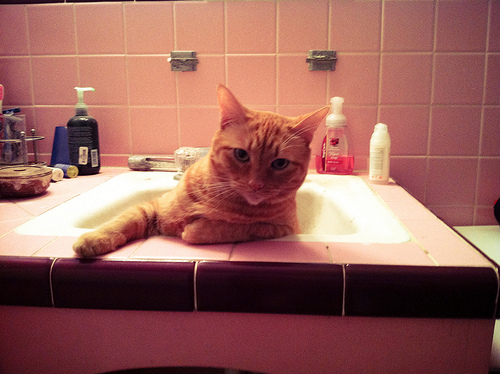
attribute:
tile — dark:
[0, 253, 54, 306]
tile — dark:
[52, 257, 194, 313]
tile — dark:
[195, 259, 343, 315]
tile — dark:
[342, 262, 499, 321]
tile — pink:
[373, 96, 436, 161]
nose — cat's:
[240, 161, 270, 199]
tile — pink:
[377, 2, 441, 57]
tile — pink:
[372, 46, 438, 111]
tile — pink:
[119, 47, 183, 112]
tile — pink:
[24, 46, 82, 111]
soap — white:
[358, 96, 431, 202]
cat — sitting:
[52, 90, 376, 314]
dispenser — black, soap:
[67, 85, 102, 173]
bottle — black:
[65, 85, 102, 176]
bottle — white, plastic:
[347, 107, 413, 188]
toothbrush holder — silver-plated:
[1, 104, 49, 166]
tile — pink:
[425, 54, 495, 181]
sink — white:
[94, 154, 389, 261]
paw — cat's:
[62, 218, 131, 270]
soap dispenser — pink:
[313, 91, 363, 186]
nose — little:
[240, 180, 267, 204]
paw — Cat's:
[69, 220, 119, 262]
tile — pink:
[123, 98, 178, 154]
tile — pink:
[376, 49, 432, 110]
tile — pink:
[225, 56, 278, 112]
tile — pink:
[126, 105, 179, 157]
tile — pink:
[22, 3, 80, 57]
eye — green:
[228, 144, 254, 172]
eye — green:
[265, 157, 296, 173]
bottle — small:
[363, 121, 392, 186]